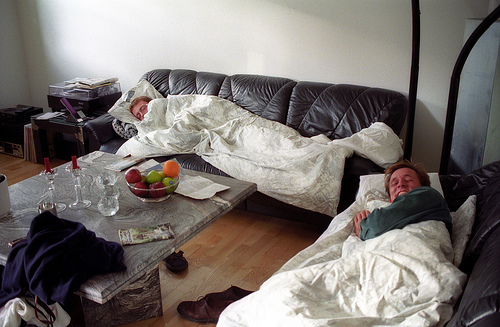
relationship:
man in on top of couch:
[128, 97, 342, 157] [81, 68, 406, 216]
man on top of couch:
[352, 159, 453, 326] [439, 160, 500, 327]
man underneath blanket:
[128, 97, 342, 157] [115, 94, 406, 216]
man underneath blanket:
[352, 159, 453, 326] [216, 220, 468, 326]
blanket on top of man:
[115, 94, 406, 216] [128, 97, 342, 157]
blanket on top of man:
[216, 220, 468, 326] [352, 159, 453, 326]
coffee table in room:
[0, 149, 259, 326] [3, 2, 499, 326]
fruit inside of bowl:
[124, 160, 180, 196] [124, 183, 179, 204]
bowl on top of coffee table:
[124, 183, 179, 204] [0, 149, 259, 326]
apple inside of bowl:
[124, 168, 142, 185] [124, 183, 179, 204]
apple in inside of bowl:
[132, 181, 147, 196] [124, 183, 179, 204]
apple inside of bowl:
[147, 182, 168, 199] [124, 183, 179, 204]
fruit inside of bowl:
[162, 160, 181, 179] [124, 183, 179, 204]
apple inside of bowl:
[144, 169, 164, 183] [124, 183, 179, 204]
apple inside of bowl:
[162, 177, 179, 194] [124, 183, 179, 204]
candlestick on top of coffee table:
[39, 171, 66, 215] [0, 149, 259, 326]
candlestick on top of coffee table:
[66, 165, 92, 210] [0, 149, 259, 326]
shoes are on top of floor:
[175, 285, 255, 324] [1, 153, 329, 327]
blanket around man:
[115, 94, 406, 216] [128, 97, 342, 157]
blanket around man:
[216, 220, 468, 326] [352, 159, 453, 326]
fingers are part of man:
[352, 209, 370, 237] [352, 159, 453, 326]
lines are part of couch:
[166, 68, 172, 93] [81, 68, 406, 216]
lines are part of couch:
[192, 70, 200, 95] [81, 68, 406, 216]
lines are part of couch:
[283, 80, 299, 125] [81, 68, 406, 216]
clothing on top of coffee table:
[0, 211, 127, 307] [0, 149, 259, 326]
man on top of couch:
[128, 97, 342, 157] [81, 68, 406, 216]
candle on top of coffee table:
[41, 156, 54, 173] [0, 149, 259, 326]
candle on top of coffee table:
[70, 154, 82, 169] [0, 149, 259, 326]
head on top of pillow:
[128, 97, 152, 123] [106, 78, 166, 131]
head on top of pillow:
[382, 161, 430, 204] [358, 173, 446, 205]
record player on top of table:
[47, 76, 122, 113] [34, 112, 113, 164]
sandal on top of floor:
[160, 250, 189, 273] [1, 153, 329, 327]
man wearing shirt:
[352, 159, 453, 326] [359, 185, 453, 242]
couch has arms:
[81, 68, 406, 216] [83, 113, 119, 152]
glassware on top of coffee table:
[96, 170, 121, 217] [0, 149, 259, 326]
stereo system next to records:
[0, 141, 23, 160] [22, 124, 36, 162]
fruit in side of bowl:
[124, 160, 180, 196] [124, 183, 179, 204]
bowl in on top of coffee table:
[124, 183, 179, 204] [0, 149, 259, 326]